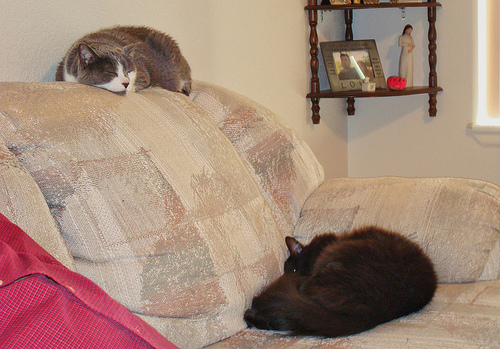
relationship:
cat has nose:
[58, 24, 193, 97] [121, 82, 128, 87]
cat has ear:
[58, 24, 193, 97] [122, 36, 143, 60]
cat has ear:
[58, 24, 193, 97] [77, 40, 98, 69]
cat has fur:
[58, 24, 193, 97] [121, 26, 171, 63]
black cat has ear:
[246, 225, 438, 340] [283, 233, 304, 258]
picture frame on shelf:
[317, 34, 392, 96] [302, 81, 445, 99]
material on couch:
[1, 212, 176, 347] [2, 81, 500, 348]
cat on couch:
[58, 24, 193, 97] [2, 81, 500, 348]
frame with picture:
[316, 37, 390, 94] [330, 47, 377, 85]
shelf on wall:
[301, 2, 442, 123] [208, 12, 288, 76]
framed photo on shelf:
[331, 49, 375, 80] [301, 2, 442, 123]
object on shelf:
[383, 75, 411, 87] [408, 84, 425, 94]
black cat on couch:
[246, 225, 438, 340] [2, 81, 500, 348]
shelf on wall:
[301, 2, 442, 123] [346, 2, 497, 187]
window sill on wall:
[462, 114, 497, 149] [2, 1, 494, 189]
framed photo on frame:
[331, 49, 375, 80] [320, 36, 388, 93]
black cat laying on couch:
[246, 225, 438, 340] [2, 19, 466, 345]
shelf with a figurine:
[301, 0, 444, 125] [394, 17, 419, 88]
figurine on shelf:
[378, 22, 419, 79] [304, 80, 443, 112]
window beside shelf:
[479, 1, 498, 108] [290, 0, 442, 99]